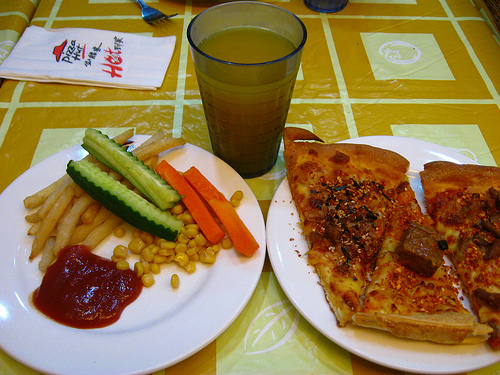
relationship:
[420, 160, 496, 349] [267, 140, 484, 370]
pizza on a plate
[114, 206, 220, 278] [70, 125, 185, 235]
corn under carrots and zucchini sticks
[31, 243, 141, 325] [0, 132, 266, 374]
ketchup on a plate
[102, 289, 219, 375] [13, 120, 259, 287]
plate with food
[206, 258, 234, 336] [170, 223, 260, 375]
carrot sticks on plate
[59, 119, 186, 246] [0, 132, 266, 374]
zucchini on plate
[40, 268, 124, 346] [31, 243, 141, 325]
big blob of ketchup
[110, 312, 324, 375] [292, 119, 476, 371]
plate with pizza